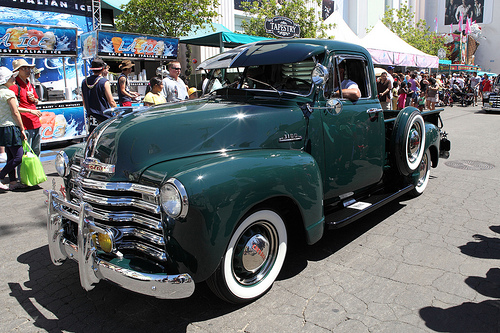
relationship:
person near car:
[0, 66, 28, 190] [43, 38, 450, 306]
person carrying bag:
[0, 66, 28, 190] [19, 139, 47, 187]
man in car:
[326, 59, 361, 101] [43, 38, 450, 306]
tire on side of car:
[392, 106, 426, 178] [43, 38, 450, 306]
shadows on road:
[1, 99, 500, 331] [0, 100, 500, 332]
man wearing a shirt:
[326, 59, 361, 101] [326, 76, 360, 97]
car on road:
[43, 38, 450, 306] [0, 100, 500, 332]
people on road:
[0, 56, 500, 196] [0, 100, 500, 332]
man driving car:
[326, 59, 361, 101] [43, 38, 450, 306]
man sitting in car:
[326, 59, 361, 101] [43, 38, 450, 306]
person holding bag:
[0, 66, 28, 190] [19, 139, 47, 187]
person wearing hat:
[0, 64, 33, 191] [0, 66, 20, 84]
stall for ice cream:
[1, 0, 180, 145] [1, 1, 181, 151]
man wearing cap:
[82, 61, 116, 136] [89, 57, 108, 73]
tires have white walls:
[207, 107, 432, 305] [224, 115, 430, 299]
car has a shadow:
[43, 38, 450, 306] [8, 174, 440, 331]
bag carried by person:
[19, 139, 47, 187] [0, 64, 33, 191]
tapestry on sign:
[269, 21, 298, 34] [265, 15, 302, 38]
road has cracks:
[0, 100, 500, 332] [0, 142, 499, 332]